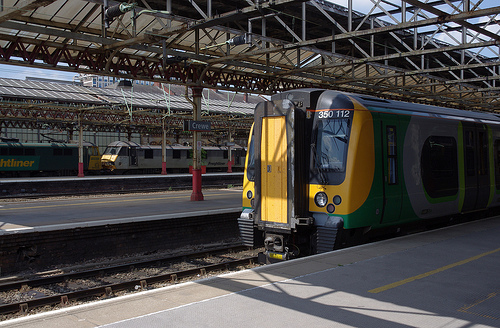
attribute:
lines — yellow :
[192, 279, 429, 326]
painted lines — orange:
[358, 240, 499, 326]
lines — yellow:
[362, 254, 499, 311]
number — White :
[313, 107, 333, 119]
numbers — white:
[310, 107, 355, 121]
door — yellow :
[245, 123, 315, 244]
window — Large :
[415, 119, 466, 206]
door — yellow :
[257, 116, 290, 224]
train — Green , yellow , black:
[238, 85, 499, 260]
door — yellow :
[259, 105, 290, 226]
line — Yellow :
[368, 244, 494, 299]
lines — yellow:
[365, 252, 497, 315]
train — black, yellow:
[101, 138, 247, 177]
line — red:
[311, 102, 352, 112]